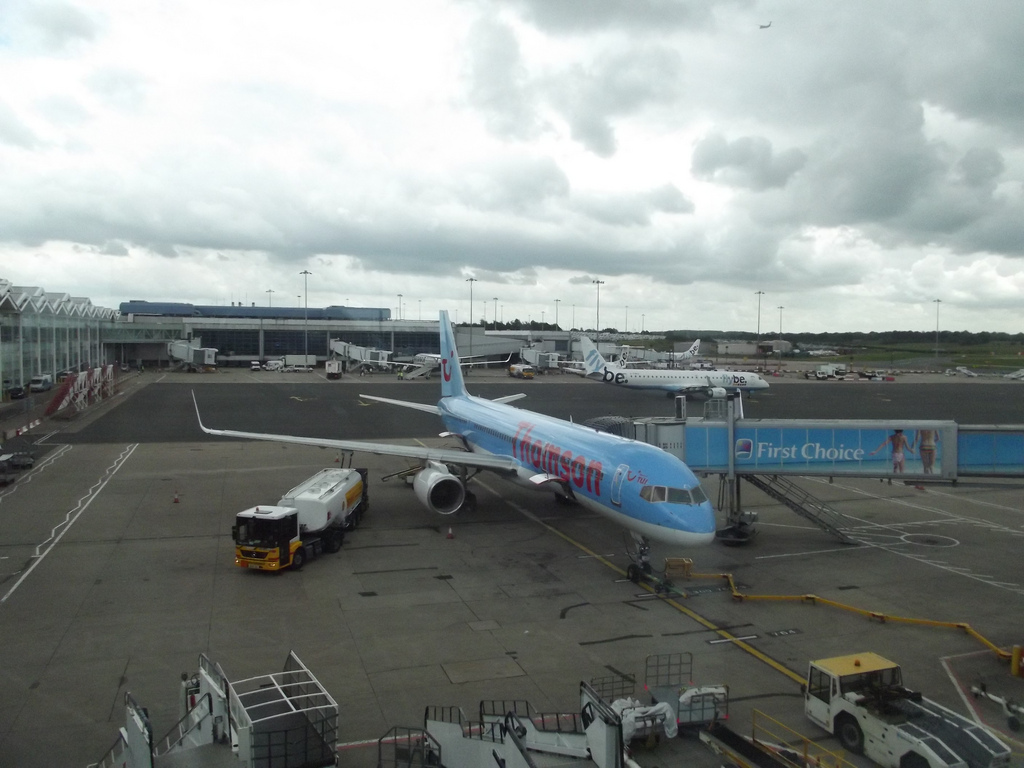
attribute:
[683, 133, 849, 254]
clouds — large, white, grey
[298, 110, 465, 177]
sky — grey, white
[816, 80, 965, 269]
sky — blue, white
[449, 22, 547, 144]
cloud — White , fluffy 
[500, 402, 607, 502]
lettering — red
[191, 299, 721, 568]
plane — blue, white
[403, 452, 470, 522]
engine — white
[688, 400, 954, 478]
billboard — blue, white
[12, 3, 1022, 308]
clouds — white, puffy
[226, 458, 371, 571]
truck — white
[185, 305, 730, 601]
plane — light blue, grey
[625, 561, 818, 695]
line — yellow 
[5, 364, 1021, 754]
tarmac — dark grey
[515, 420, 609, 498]
logo — red 